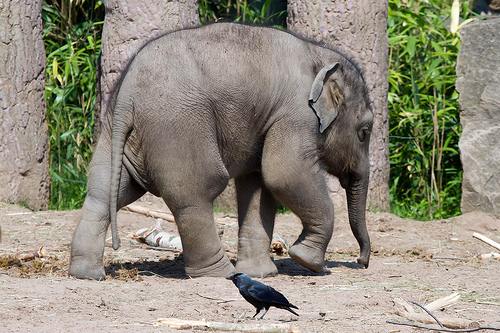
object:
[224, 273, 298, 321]
bird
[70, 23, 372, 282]
elephant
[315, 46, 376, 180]
head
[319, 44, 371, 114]
hair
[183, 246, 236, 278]
foot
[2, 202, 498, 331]
ground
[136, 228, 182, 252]
stone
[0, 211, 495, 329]
road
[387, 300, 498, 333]
twig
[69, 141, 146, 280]
legs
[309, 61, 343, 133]
ear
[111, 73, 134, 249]
tail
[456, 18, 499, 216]
rock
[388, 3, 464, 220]
foliage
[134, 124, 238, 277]
leg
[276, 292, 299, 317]
tail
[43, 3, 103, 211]
leaves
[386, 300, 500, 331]
stick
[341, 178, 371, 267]
trunk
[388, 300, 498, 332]
tree branches